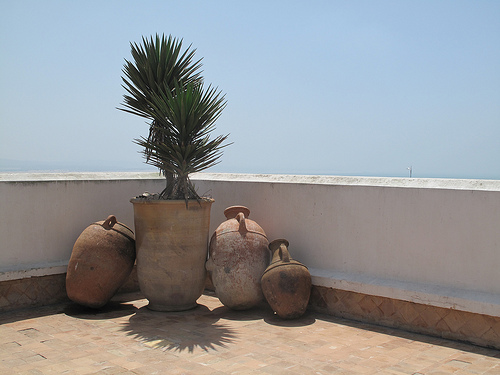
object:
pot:
[261, 239, 314, 319]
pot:
[65, 215, 137, 309]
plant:
[116, 31, 232, 200]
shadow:
[116, 303, 239, 354]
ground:
[2, 283, 500, 373]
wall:
[2, 172, 499, 317]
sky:
[2, 2, 499, 176]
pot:
[205, 205, 272, 309]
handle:
[100, 214, 117, 230]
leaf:
[166, 42, 194, 78]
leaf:
[177, 57, 204, 78]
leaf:
[193, 82, 213, 115]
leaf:
[115, 107, 154, 121]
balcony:
[0, 170, 499, 373]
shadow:
[63, 302, 139, 320]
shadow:
[211, 305, 274, 321]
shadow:
[263, 313, 315, 328]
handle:
[233, 211, 249, 231]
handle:
[279, 243, 291, 263]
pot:
[129, 196, 215, 311]